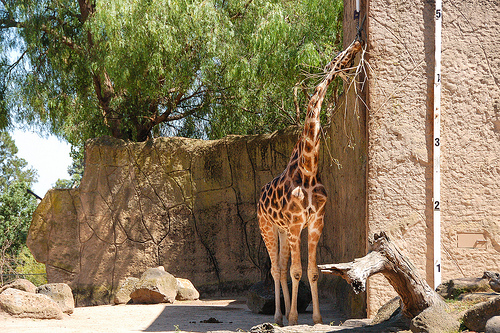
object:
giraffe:
[255, 37, 367, 327]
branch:
[290, 30, 377, 150]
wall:
[330, 0, 499, 331]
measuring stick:
[433, 2, 441, 292]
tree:
[1, 2, 350, 140]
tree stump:
[316, 229, 452, 330]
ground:
[10, 294, 498, 331]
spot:
[300, 154, 314, 171]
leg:
[281, 223, 307, 326]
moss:
[444, 286, 460, 302]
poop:
[188, 315, 232, 325]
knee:
[291, 267, 303, 279]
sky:
[0, 0, 227, 196]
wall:
[30, 129, 330, 302]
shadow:
[144, 303, 353, 330]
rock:
[129, 264, 181, 303]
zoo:
[5, 1, 500, 330]